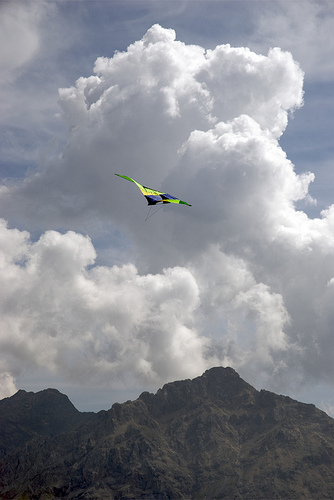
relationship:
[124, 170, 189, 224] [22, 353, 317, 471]
parasail over mountain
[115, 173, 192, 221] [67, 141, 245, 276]
parasail in air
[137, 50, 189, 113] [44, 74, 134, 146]
cloud in sky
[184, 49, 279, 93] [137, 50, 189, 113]
light in cloud